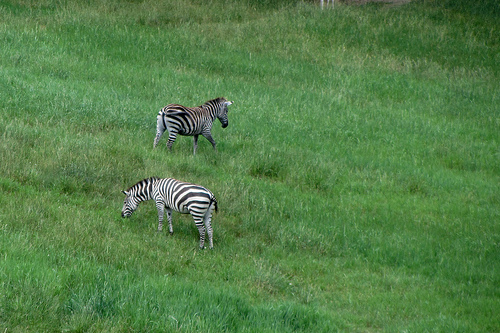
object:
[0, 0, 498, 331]
field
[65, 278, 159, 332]
grass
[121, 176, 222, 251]
zebra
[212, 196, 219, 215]
tail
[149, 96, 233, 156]
zebra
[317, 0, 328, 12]
trunk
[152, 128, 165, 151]
legs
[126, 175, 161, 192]
mane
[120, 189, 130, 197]
ears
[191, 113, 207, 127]
pattern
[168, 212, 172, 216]
spot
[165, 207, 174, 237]
leg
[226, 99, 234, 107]
ear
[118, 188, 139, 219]
head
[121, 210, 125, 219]
nose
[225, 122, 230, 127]
nose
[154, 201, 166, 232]
legs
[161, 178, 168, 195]
stripes